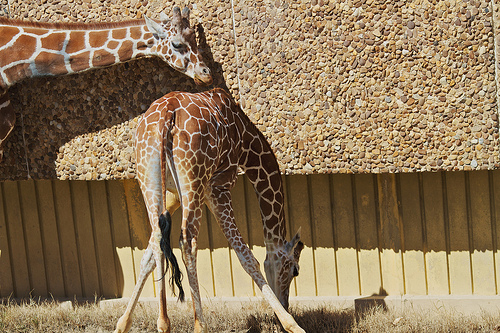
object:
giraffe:
[0, 1, 216, 146]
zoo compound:
[1, 1, 499, 332]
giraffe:
[65, 67, 368, 333]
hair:
[131, 212, 203, 293]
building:
[246, 12, 474, 182]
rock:
[330, 36, 463, 116]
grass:
[15, 293, 339, 327]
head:
[104, 225, 211, 304]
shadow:
[353, 287, 392, 328]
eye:
[281, 257, 304, 282]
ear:
[277, 225, 310, 274]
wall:
[267, 1, 480, 152]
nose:
[275, 279, 291, 307]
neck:
[213, 144, 319, 224]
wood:
[331, 179, 391, 292]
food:
[207, 309, 318, 329]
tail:
[139, 132, 192, 302]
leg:
[97, 202, 169, 309]